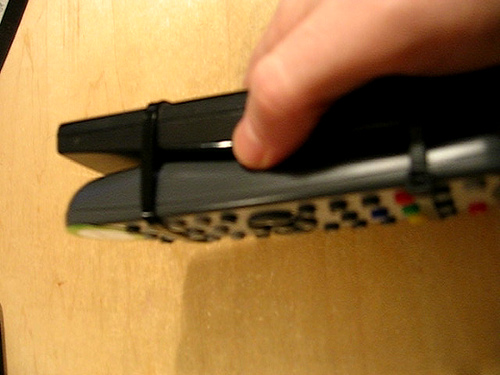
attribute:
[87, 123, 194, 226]
remotes — together, black, grey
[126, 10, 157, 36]
table — brown, wooden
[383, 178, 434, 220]
button — yellow, green, colorful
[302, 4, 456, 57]
hand — white